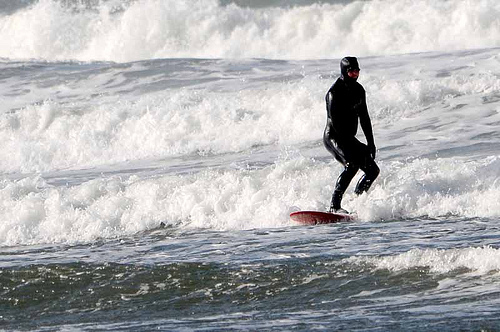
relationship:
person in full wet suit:
[324, 57, 381, 214] [325, 57, 377, 213]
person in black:
[324, 57, 381, 214] [324, 56, 381, 213]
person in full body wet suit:
[324, 57, 381, 214] [325, 57, 377, 213]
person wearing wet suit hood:
[324, 57, 381, 214] [340, 57, 361, 81]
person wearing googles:
[324, 57, 381, 214] [345, 66, 360, 73]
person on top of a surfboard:
[324, 57, 381, 214] [290, 210, 360, 227]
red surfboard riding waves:
[290, 210, 360, 227] [2, 156, 500, 229]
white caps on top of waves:
[7, 4, 500, 247] [2, 156, 500, 229]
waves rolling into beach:
[2, 156, 500, 229] [4, 243, 499, 328]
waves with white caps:
[2, 156, 500, 229] [7, 4, 500, 247]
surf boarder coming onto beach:
[324, 57, 381, 214] [4, 243, 499, 328]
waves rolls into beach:
[0, 0, 497, 60] [4, 243, 499, 328]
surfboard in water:
[290, 210, 360, 227] [3, 5, 493, 326]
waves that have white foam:
[2, 156, 500, 229] [3, 4, 500, 270]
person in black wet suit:
[324, 57, 381, 214] [325, 57, 377, 213]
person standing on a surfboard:
[324, 57, 381, 214] [290, 210, 360, 227]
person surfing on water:
[324, 57, 381, 214] [3, 5, 493, 326]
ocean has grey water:
[3, 5, 493, 326] [3, 5, 493, 326]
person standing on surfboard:
[324, 57, 381, 214] [290, 210, 360, 227]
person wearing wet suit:
[324, 57, 381, 214] [325, 57, 377, 213]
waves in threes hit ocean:
[5, 2, 498, 250] [3, 5, 493, 326]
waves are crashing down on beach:
[2, 156, 500, 229] [4, 243, 499, 328]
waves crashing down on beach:
[0, 0, 497, 60] [4, 243, 499, 328]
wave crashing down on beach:
[2, 156, 500, 229] [4, 243, 499, 328]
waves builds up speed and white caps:
[0, 0, 497, 60] [7, 4, 500, 247]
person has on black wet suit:
[324, 57, 381, 214] [325, 57, 377, 213]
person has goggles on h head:
[324, 57, 381, 214] [339, 56, 360, 80]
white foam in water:
[3, 4, 500, 270] [3, 5, 493, 326]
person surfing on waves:
[324, 57, 381, 214] [2, 156, 500, 229]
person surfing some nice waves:
[324, 57, 381, 214] [2, 156, 500, 229]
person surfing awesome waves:
[324, 57, 381, 214] [2, 156, 500, 229]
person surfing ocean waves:
[324, 57, 381, 214] [2, 156, 500, 229]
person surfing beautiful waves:
[324, 57, 381, 214] [2, 156, 500, 229]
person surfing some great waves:
[324, 57, 381, 214] [2, 156, 500, 229]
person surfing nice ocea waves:
[324, 57, 381, 214] [2, 156, 500, 229]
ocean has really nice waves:
[3, 5, 493, 326] [5, 2, 498, 250]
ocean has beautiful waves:
[3, 5, 493, 326] [5, 2, 498, 250]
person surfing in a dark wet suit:
[324, 57, 381, 214] [325, 57, 377, 213]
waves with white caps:
[5, 2, 498, 250] [7, 4, 500, 247]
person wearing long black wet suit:
[324, 57, 381, 214] [325, 57, 377, 213]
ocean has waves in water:
[3, 5, 493, 326] [3, 5, 493, 326]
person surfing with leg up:
[324, 57, 381, 214] [325, 136, 360, 213]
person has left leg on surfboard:
[324, 57, 381, 214] [290, 210, 360, 227]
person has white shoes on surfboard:
[324, 57, 381, 214] [290, 210, 360, 227]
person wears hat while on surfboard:
[324, 57, 381, 214] [290, 210, 360, 227]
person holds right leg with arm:
[324, 57, 381, 214] [361, 112, 378, 158]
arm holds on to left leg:
[361, 112, 378, 158] [354, 139, 380, 204]